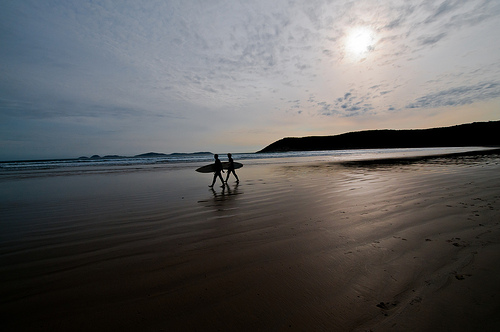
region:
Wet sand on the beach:
[192, 231, 291, 294]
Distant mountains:
[256, 119, 497, 157]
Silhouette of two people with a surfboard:
[190, 150, 251, 192]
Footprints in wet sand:
[432, 193, 493, 222]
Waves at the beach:
[45, 158, 126, 175]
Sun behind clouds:
[333, 16, 394, 70]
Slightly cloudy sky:
[107, 53, 187, 125]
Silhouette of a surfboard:
[194, 159, 248, 175]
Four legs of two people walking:
[202, 171, 250, 190]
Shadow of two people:
[192, 187, 257, 213]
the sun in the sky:
[343, 24, 388, 54]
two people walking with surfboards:
[192, 146, 244, 196]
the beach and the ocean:
[1, 152, 498, 329]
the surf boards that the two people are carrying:
[194, 160, 244, 176]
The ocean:
[0, 145, 498, 179]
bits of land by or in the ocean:
[0, 116, 497, 163]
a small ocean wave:
[2, 155, 359, 170]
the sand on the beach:
[11, 221, 497, 329]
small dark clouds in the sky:
[303, 75, 498, 119]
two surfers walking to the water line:
[188, 148, 246, 198]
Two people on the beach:
[202, 151, 242, 188]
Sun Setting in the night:
[305, 13, 403, 103]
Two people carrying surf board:
[195, 150, 246, 191]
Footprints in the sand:
[397, 213, 484, 287]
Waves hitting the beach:
[113, 144, 414, 155]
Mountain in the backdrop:
[270, 127, 498, 144]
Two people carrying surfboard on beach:
[196, 152, 247, 186]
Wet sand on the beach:
[56, 148, 171, 198]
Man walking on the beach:
[193, 150, 225, 197]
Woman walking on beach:
[223, 153, 248, 192]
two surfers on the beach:
[160, 123, 277, 219]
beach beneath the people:
[117, 178, 182, 237]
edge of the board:
[180, 156, 211, 184]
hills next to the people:
[312, 100, 397, 151]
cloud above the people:
[150, 57, 220, 107]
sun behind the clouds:
[296, 25, 381, 97]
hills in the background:
[75, 126, 155, 171]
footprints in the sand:
[380, 205, 485, 310]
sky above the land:
[81, 86, 176, 136]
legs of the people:
[199, 174, 255, 194]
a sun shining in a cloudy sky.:
[326, 14, 388, 65]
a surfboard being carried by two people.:
[196, 154, 241, 182]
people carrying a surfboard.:
[179, 145, 244, 195]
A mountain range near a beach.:
[254, 111, 498, 161]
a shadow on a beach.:
[203, 184, 249, 212]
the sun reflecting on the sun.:
[317, 162, 414, 253]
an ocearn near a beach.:
[0, 150, 493, 180]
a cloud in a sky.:
[295, 81, 390, 127]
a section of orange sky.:
[215, 98, 497, 129]